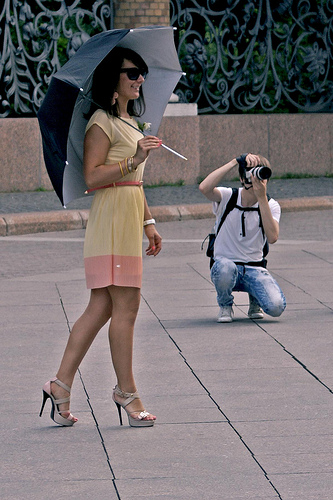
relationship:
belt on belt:
[93, 182, 144, 190] [83, 179, 144, 195]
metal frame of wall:
[0, 1, 332, 118] [1, 0, 331, 193]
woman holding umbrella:
[45, 46, 157, 429] [34, 21, 188, 429]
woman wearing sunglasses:
[45, 46, 157, 429] [118, 64, 150, 79]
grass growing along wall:
[272, 168, 331, 179] [1, 115, 318, 180]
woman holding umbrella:
[45, 46, 157, 429] [24, 25, 203, 182]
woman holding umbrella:
[45, 46, 157, 429] [35, 25, 183, 210]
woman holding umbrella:
[45, 46, 157, 429] [51, 31, 171, 220]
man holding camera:
[197, 145, 290, 324] [232, 146, 276, 193]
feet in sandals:
[52, 401, 89, 425] [109, 376, 157, 431]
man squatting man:
[197, 145, 290, 324] [197, 145, 290, 324]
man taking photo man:
[197, 145, 290, 324] [197, 145, 290, 324]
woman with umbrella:
[45, 46, 157, 429] [23, 23, 201, 210]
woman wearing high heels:
[45, 46, 157, 429] [29, 365, 157, 430]